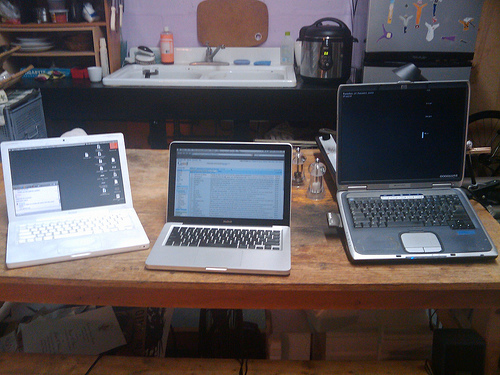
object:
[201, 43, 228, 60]
faucet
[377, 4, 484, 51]
magnets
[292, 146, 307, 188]
shaker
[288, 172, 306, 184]
pepper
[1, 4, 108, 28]
shelf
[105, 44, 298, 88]
sink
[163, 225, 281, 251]
keys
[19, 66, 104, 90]
counter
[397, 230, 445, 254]
touch pad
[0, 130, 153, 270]
laptop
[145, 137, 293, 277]
laptop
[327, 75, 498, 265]
laptop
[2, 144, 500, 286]
surface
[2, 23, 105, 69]
shelf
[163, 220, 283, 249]
keyboard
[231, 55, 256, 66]
soap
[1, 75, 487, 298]
three open laptop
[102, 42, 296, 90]
white double sink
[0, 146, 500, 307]
countertop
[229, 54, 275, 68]
two bars of soap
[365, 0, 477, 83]
silver refrigerator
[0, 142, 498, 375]
wooden table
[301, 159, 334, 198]
pepper shakers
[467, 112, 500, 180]
bicycle wheel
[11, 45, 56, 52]
white dishes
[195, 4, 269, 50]
brown cutting board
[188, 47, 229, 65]
dish soap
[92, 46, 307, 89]
silver sink facet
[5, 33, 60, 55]
plates on shelf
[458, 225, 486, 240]
company logo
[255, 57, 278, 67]
blue dish sponge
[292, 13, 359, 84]
rice cooker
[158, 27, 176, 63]
bottle of hand soap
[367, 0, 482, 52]
refrigerator magnets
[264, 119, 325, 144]
paper in trashcan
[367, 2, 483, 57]
refrigerator door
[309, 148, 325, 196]
clear glass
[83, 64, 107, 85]
white cup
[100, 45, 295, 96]
sink is white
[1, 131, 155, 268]
laptop is white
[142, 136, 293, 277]
laptop is gray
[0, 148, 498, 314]
wooden surface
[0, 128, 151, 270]
laptops are on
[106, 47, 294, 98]
sink is dirty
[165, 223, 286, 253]
keyboard is black